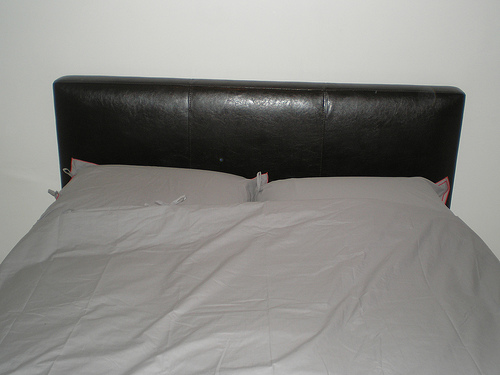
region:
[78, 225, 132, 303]
wrinkles on a bedsheet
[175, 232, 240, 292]
wrinkles on a bedsheetwrinkles on a bedsheet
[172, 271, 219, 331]
wrinkles on a bedsheet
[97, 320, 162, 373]
wrinkles on a bedsheet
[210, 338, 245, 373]
wrinkles on a bedsheet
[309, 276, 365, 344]
wrinkles on a bedsheet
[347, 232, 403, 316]
wrinkles on a bedsheet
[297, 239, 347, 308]
wrinkles on a bedsheet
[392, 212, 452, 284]
wrinkles on a bedsheet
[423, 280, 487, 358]
wrinkles on a bedsheet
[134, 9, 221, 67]
a clean white wall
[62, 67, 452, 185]
a big brown leather head board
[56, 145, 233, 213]
a pillow on the left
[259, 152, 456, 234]
a pillow on the right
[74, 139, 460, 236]
some pillows on the bed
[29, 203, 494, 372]
a grey blanket on a bed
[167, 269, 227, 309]
a wrinkle on a blanket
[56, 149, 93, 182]
the corner of a pillow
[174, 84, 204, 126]
a wrinkle in some leather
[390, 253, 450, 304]
a crease on a blanket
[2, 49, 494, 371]
this is a bed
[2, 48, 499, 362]
a bed that has been made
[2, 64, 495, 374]
the bed is made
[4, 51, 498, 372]
a neatly made bed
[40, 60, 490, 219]
this is the headboard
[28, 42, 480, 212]
the headboard is against the wall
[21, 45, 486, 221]
the headboard is black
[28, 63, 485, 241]
this is a leather headboard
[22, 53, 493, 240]
a black leather headboard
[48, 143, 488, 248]
the pillowcases have a red trim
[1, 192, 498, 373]
White comforter on a bed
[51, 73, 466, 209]
Black leather headboard with 3 sections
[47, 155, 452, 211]
Two pillows in white pillow cases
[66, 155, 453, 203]
Red design on the corners of pillow cases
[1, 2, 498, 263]
White wall with no pictures on it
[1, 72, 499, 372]
Bed with a black headboard against a white wall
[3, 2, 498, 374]
Bedroom with a black and white color scheme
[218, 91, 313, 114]
Light shining off black leather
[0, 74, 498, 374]
Double bed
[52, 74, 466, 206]
Plain, square headboard on a bed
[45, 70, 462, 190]
Black headboard on the bed.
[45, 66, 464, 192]
Black headboard covered in leather.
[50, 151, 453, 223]
Two pillows on top of the bed.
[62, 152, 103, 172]
Red trim on the pillow case of the pillow.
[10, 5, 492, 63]
Wall that is painted white.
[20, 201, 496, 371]
Grey sheet covering the bed.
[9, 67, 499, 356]
An empty bed with no one in it.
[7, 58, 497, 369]
Bed that is made and not messy.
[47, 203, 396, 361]
Sheet with some wrinkles in it.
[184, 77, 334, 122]
Reflection of the light shining on the headboard.